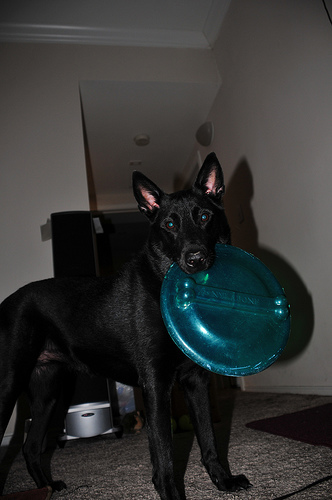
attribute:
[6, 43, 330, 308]
walls — beige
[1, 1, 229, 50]
ceiling — white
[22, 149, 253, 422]
dog — black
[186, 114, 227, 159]
light — wall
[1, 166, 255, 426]
dog — black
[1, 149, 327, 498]
dog — black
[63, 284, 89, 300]
fur — skinny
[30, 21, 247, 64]
moulding — white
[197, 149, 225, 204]
ear — dog's, perked up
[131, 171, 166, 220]
ear — perked up, dog's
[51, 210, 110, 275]
speaker — black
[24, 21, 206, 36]
molding — white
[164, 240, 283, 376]
frisbee — shiny blue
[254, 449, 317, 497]
carpet — grey